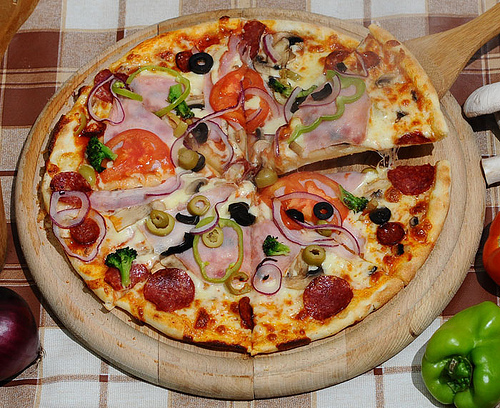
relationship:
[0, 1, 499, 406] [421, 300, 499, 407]
table has pepper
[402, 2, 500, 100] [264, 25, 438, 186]
handle under pizza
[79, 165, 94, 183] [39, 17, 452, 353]
green olives on pizza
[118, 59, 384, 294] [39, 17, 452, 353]
cheese on pizza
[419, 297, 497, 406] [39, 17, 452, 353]
bell pepper on pizza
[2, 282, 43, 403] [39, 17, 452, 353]
onion near pizza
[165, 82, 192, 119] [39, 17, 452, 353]
vegetables on pizza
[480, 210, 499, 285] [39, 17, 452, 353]
tomato near pizza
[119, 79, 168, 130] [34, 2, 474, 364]
ham on pizza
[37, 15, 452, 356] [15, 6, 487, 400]
pizza in board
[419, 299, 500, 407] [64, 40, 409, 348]
bell pepper next to pizza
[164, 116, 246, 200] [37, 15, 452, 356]
olive on pizza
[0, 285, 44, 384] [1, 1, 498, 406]
onion on tablecloth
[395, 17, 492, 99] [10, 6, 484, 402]
handle of board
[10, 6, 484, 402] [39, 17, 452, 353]
board holding pizza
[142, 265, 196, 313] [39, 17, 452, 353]
pepperoni on pizza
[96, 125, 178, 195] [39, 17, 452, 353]
tomato on pizza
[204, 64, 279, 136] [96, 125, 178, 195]
tomato on tomato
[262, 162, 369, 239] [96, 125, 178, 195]
tomato on tomato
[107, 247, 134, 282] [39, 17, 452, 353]
broccoli on pizza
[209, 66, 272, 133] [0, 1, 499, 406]
tomato on table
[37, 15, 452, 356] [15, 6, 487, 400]
pizza sitting on board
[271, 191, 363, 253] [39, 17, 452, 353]
red onion by pizza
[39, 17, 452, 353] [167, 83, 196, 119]
pizza with vegetables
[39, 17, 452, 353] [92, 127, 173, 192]
pizza with tomato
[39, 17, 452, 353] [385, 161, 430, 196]
pizza with pepperoni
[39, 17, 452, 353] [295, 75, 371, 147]
pizza with ham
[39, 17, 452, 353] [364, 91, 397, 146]
pizza with cheese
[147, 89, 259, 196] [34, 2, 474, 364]
mushrooms by pizza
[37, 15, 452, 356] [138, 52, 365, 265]
pizza with topping